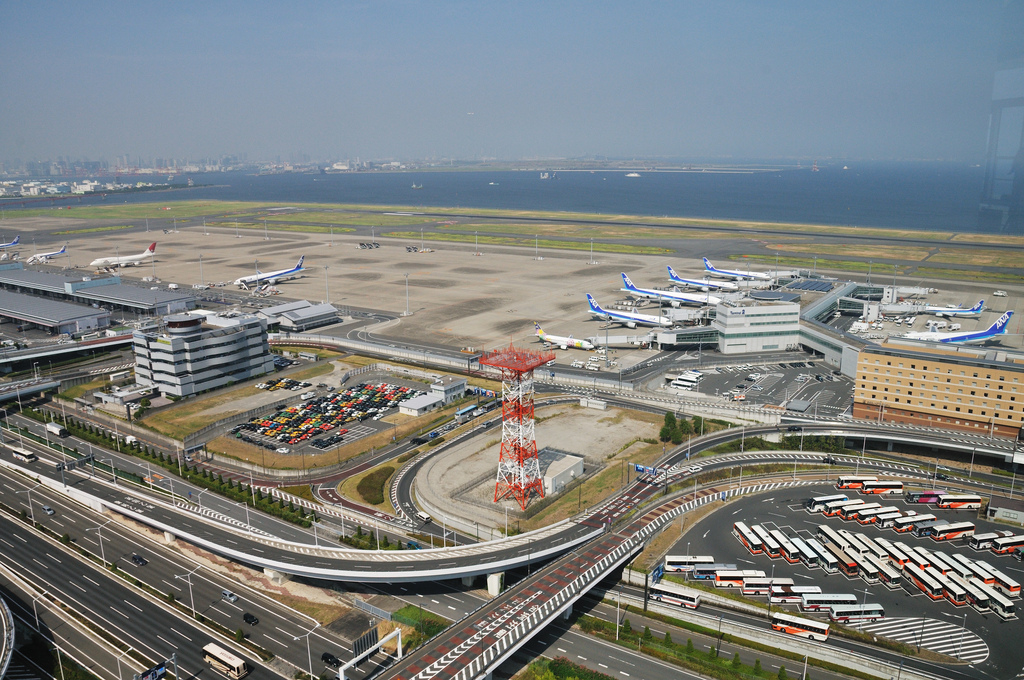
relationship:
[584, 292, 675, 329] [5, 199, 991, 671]
airplane parked at airport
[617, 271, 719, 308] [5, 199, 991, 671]
airplane parked at airport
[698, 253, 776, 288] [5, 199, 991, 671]
plane parked at airport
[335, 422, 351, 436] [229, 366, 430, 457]
car parked in parking lot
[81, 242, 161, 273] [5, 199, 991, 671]
airplane parked at airport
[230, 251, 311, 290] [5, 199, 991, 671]
airplane parked at airport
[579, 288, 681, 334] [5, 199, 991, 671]
airplane parked at airport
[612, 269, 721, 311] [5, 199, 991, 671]
airplane parked at airport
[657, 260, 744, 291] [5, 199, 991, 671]
airplane parked at airport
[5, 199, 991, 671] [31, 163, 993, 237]
airport built next to water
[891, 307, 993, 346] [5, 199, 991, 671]
plane parked at airport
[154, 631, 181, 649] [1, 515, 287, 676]
line painted on road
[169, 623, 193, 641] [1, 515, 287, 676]
line painted on road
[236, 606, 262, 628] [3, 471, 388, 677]
car driving on highway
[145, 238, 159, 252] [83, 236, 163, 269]
tail attached to airplane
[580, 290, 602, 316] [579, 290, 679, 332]
tail attached to airplane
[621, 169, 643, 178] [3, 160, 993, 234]
boat riding in water